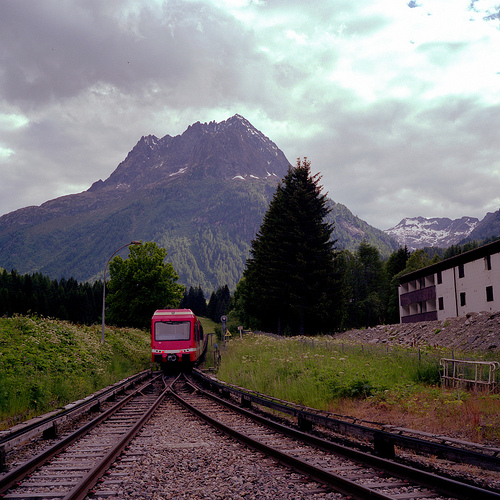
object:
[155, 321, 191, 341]
windshield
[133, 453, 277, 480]
rocks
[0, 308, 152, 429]
grass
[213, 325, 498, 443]
grass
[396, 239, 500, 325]
building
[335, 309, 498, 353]
hill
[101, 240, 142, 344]
lamp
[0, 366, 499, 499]
railroad tracks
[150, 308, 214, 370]
train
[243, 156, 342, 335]
tree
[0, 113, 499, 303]
mountain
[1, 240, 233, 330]
trees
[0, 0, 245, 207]
clouds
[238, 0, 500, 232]
clouds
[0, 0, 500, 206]
sky